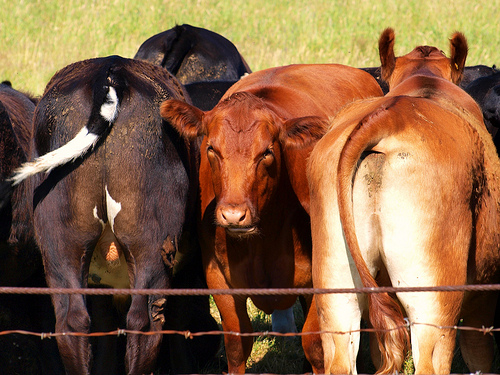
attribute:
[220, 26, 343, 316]
cow — brown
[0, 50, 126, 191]
tail — white, black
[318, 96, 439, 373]
tail — on cow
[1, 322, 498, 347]
wire — rusty, barbed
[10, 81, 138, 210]
tail — next to cow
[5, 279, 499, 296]
wire — rusted, metal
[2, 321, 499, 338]
wire — metal, rusted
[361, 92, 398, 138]
ground — next to cow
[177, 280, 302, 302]
barb wire — rusty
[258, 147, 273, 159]
eye — on cow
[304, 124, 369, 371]
leg — next to cow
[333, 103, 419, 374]
tail — swinging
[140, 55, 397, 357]
cow — brown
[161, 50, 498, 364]
cow — brown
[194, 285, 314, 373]
ground — next to cow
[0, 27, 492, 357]
herd — large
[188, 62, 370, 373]
cows — brown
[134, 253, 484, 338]
fence — next to cow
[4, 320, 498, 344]
wire fence — rusted, barbed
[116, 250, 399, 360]
wire — rusty, barbed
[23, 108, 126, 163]
tail — black, white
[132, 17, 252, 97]
cow — black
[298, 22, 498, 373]
cow — brown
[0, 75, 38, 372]
cow — black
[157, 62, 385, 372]
cow — brown